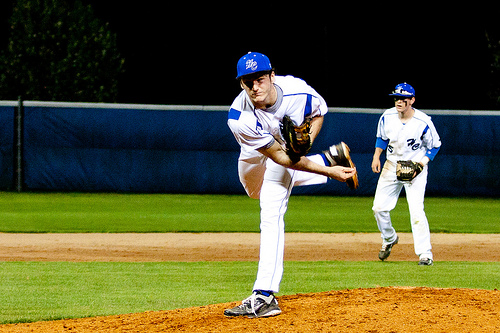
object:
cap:
[236, 52, 273, 79]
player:
[370, 82, 440, 266]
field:
[0, 191, 500, 331]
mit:
[395, 160, 423, 182]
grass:
[1, 193, 498, 323]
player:
[223, 52, 357, 319]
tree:
[1, 0, 128, 103]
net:
[0, 0, 498, 111]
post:
[15, 93, 24, 192]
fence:
[0, 101, 499, 199]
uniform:
[372, 107, 442, 260]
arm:
[229, 120, 329, 176]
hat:
[388, 82, 416, 98]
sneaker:
[224, 293, 281, 317]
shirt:
[375, 106, 442, 163]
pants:
[371, 161, 432, 255]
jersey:
[227, 75, 329, 157]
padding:
[0, 105, 499, 199]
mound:
[0, 285, 499, 333]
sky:
[1, 0, 500, 112]